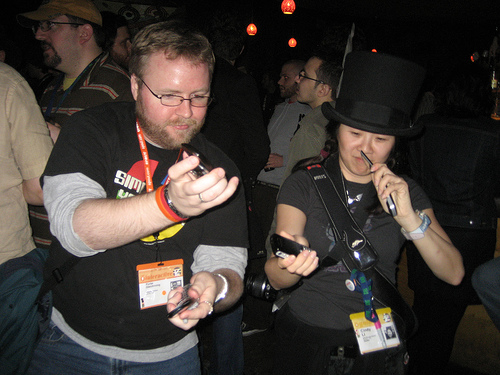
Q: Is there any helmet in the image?
A: No, there are no helmets.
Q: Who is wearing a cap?
A: The man is wearing a cap.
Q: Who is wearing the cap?
A: The man is wearing a cap.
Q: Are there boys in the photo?
A: No, there are no boys.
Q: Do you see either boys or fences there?
A: No, there are no boys or fences.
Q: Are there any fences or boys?
A: No, there are no boys or fences.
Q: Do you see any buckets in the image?
A: No, there are no buckets.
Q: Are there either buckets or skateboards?
A: No, there are no buckets or skateboards.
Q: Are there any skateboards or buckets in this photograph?
A: No, there are no buckets or skateboards.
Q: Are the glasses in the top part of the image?
A: Yes, the glasses are in the top of the image.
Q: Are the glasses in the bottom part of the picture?
A: No, the glasses are in the top of the image.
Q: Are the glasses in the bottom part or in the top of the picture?
A: The glasses are in the top of the image.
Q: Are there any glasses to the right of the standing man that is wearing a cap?
A: Yes, there are glasses to the right of the man.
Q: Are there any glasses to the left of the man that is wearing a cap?
A: No, the glasses are to the right of the man.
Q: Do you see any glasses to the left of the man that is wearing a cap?
A: No, the glasses are to the right of the man.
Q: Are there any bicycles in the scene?
A: No, there are no bicycles.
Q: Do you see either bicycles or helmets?
A: No, there are no bicycles or helmets.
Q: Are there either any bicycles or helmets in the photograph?
A: No, there are no bicycles or helmets.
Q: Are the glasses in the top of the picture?
A: Yes, the glasses are in the top of the image.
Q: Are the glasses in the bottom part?
A: No, the glasses are in the top of the image.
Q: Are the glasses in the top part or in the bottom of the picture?
A: The glasses are in the top of the image.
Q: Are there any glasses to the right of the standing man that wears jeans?
A: Yes, there are glasses to the right of the man.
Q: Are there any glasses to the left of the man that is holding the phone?
A: No, the glasses are to the right of the man.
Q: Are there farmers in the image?
A: No, there are no farmers.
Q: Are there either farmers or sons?
A: No, there are no farmers or sons.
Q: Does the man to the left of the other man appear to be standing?
A: Yes, the man is standing.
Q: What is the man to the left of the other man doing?
A: The man is standing.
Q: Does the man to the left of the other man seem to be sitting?
A: No, the man is standing.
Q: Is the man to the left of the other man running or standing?
A: The man is standing.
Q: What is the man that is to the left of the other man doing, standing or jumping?
A: The man is standing.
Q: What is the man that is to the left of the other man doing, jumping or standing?
A: The man is standing.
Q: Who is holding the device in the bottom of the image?
A: The man is holding the phone.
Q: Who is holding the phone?
A: The man is holding the phone.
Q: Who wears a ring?
A: The man wears a ring.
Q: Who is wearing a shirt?
A: The man is wearing a shirt.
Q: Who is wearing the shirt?
A: The man is wearing a shirt.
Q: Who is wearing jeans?
A: The man is wearing jeans.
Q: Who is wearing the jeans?
A: The man is wearing jeans.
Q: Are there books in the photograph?
A: No, there are no books.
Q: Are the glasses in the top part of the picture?
A: Yes, the glasses are in the top of the image.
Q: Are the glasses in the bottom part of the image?
A: No, the glasses are in the top of the image.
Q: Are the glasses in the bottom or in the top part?
A: The glasses are in the top of the image.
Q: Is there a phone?
A: Yes, there is a phone.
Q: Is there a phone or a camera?
A: Yes, there is a phone.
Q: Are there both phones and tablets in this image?
A: No, there is a phone but no tablets.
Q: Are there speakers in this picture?
A: No, there are no speakers.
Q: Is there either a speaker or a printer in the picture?
A: No, there are no speakers or printers.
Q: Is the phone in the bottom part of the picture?
A: Yes, the phone is in the bottom of the image.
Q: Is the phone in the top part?
A: No, the phone is in the bottom of the image.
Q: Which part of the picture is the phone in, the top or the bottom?
A: The phone is in the bottom of the image.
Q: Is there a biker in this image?
A: No, there are no bikers.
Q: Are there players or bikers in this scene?
A: No, there are no bikers or players.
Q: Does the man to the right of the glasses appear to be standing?
A: Yes, the man is standing.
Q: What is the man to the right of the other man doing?
A: The man is standing.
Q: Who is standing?
A: The man is standing.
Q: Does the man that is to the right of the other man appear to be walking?
A: No, the man is standing.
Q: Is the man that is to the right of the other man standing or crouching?
A: The man is standing.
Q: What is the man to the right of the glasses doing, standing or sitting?
A: The man is standing.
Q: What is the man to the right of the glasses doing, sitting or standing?
A: The man is standing.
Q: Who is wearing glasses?
A: The man is wearing glasses.